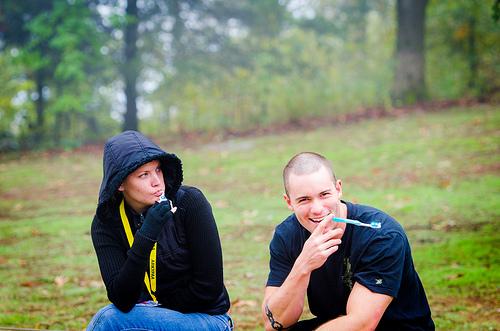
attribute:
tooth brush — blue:
[326, 212, 384, 233]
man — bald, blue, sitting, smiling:
[264, 151, 436, 331]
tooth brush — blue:
[157, 195, 178, 213]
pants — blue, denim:
[84, 303, 231, 331]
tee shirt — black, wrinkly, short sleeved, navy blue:
[267, 209, 436, 329]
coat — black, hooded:
[91, 130, 233, 317]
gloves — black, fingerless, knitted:
[154, 198, 178, 217]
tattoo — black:
[261, 310, 282, 330]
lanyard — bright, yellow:
[117, 201, 164, 302]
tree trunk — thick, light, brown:
[388, 2, 433, 107]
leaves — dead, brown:
[181, 94, 499, 146]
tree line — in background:
[4, 4, 498, 147]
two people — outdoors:
[69, 122, 440, 327]